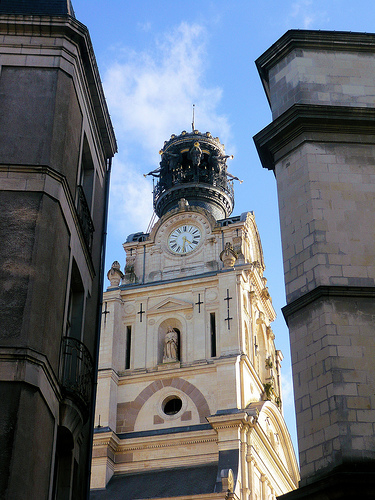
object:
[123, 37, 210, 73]
sky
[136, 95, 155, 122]
see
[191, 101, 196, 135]
pole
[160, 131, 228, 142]
roof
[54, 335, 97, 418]
rail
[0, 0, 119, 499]
building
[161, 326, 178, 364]
statue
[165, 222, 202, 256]
clock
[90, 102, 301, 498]
building